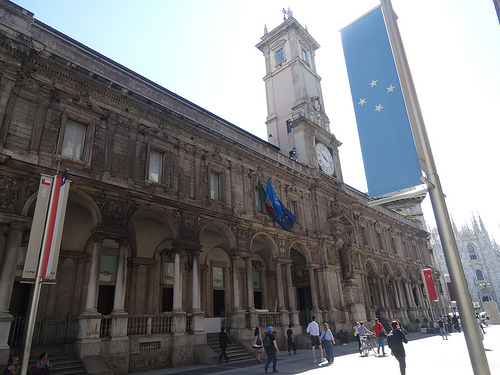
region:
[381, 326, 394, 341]
Person wearing black shirt.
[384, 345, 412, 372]
Person wearing black pants.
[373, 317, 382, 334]
Person wearing red shirt.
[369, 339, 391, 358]
Person wearing blue jeans.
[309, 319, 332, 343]
Person wearing white shirt.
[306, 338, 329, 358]
Person wearing dark shorts.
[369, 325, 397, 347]
Person has dark bag over shoulder.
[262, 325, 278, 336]
Person wearing blue hat.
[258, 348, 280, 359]
Person wearing dark pants.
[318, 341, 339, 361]
Person wearing blue pants.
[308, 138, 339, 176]
a round white clock face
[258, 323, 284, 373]
a person on the sidewalk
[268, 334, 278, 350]
the arm of a person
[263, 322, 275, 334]
the head of a person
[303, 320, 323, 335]
a white shirt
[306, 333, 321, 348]
a pair of black shorts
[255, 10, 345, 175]
a gray clock tower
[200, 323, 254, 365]
a set of steps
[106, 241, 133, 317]
a gray pillar on the building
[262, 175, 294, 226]
a blue flag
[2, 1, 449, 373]
large older-looking stone building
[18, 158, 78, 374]
long narrow sign on pole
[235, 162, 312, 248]
flag hanging from front of building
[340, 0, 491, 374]
blue banner on pole with stars on it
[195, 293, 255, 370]
person walking beside steps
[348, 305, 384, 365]
person walking with a bicycle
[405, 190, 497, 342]
Gothic cathedral in the distance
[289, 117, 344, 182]
large clock on tower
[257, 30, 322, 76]
windows on sides of tower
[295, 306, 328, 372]
tall man wearing a white shirt and dark shorts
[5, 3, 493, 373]
building along side a street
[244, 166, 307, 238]
flags hanging from a building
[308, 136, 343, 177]
clock on front of a building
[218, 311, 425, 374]
people walking on a sidewalk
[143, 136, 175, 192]
window of a building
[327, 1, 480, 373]
banner on a metal pole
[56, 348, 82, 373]
steps to a building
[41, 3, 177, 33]
blue sky in the distance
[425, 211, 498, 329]
historical building in the background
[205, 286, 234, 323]
entryway to a building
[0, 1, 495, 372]
photo taken from slanted angle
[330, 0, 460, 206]
blue flag with yellow stars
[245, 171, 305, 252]
flags hang from the building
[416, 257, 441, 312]
red and gold flag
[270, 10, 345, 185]
clock at bottom of the tower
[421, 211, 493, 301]
cathedral in the background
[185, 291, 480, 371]
pedestrians walking in front of the building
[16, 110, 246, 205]
windows covered from the inside with white curtains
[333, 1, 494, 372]
metal pole supports flag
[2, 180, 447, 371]
row of arches at front of the building